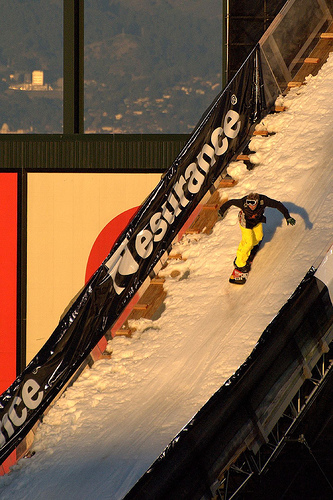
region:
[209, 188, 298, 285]
the person is snow boarding.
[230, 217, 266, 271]
person's pants are yellow.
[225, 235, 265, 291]
person standing on a board.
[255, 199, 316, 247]
shadow on the ground.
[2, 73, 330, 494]
snow covering the hill.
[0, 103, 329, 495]
the snow is white.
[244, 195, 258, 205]
person is wearing goggles.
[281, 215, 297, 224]
person is wearing gloves.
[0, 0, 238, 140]
trees in the distance.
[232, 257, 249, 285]
the man is on a snow board.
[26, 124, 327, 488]
snow on the slope.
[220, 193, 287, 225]
the man is wearing a black sweater.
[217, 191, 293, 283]
the man is balancing himself on the snow board.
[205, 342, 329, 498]
framework support of ski slope.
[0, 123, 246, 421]
black banner next to ski slope.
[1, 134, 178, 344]
red, black and tan wooden wall next to slope.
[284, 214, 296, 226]
the man is wearing gloves.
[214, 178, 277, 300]
this is a man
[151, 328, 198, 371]
the snow is white in color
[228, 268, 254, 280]
this is a surfboard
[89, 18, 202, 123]
this is a window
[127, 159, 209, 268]
this is a writing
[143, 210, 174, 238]
the writing is in white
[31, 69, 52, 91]
this is a building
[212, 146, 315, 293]
Snowboarder gears up for his big trick.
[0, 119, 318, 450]
Snowboarder flies down the massive ramp.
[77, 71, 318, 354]
Esurance banner that is next to the snowboarder.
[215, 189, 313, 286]
The snowboarder is focused on making his next move.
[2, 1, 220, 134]
A view of the surrounding city.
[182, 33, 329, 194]
Ice starts to melt on the ramp.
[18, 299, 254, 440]
The sun has melted part of the ramp's snow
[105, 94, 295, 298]
Esurance is sponsoring this snowboarding competition.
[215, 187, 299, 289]
a snowboard careens down a ramp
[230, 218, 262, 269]
snowboard dude is wearing yellow pants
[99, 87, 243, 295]
esurance is a sponsor of this event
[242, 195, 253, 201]
snowboard dude is wearing dark sunglasses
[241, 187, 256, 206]
snowboard dude is not wearing a helmet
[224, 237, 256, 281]
snowboard dude's board is red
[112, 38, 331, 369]
this ramp is really steep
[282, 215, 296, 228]
snowboard dude is wearing black gloves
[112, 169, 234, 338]
some of the actual wooden ramp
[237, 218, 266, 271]
man is wearing pants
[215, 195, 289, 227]
man is wearing a jacket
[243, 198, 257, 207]
man is wearing goggles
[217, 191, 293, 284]
man is on a snowboard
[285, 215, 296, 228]
man is wearing glove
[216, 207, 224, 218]
man is wearing glove